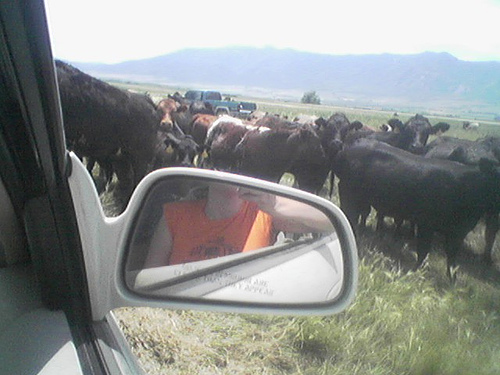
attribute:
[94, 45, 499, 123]
mountain — clearing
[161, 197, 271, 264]
shirt — orange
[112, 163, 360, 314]
mirror — white, reflecting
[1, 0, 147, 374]
truck — blue, green, distant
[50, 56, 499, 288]
cattle — standing, black, brown, herding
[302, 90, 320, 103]
bush — green, alone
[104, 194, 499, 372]
grass — grassy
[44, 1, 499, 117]
sky — above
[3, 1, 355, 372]
car — black